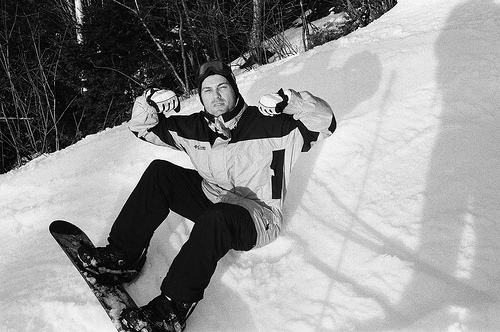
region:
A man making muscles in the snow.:
[78, 57, 337, 329]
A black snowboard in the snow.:
[48, 219, 160, 330]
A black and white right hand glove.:
[146, 84, 181, 113]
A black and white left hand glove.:
[254, 92, 289, 116]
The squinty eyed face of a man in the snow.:
[201, 74, 231, 114]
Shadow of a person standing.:
[395, 0, 498, 330]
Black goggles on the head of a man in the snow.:
[195, 62, 232, 78]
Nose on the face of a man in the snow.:
[210, 87, 221, 102]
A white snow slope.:
[3, 2, 499, 329]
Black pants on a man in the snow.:
[108, 159, 255, 304]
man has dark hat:
[185, 65, 236, 91]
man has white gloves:
[142, 80, 289, 127]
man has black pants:
[95, 173, 270, 283]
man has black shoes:
[94, 220, 158, 320]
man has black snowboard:
[29, 203, 138, 324]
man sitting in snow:
[137, 48, 307, 325]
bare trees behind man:
[0, 13, 293, 130]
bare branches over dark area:
[5, 5, 305, 166]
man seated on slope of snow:
[6, 1, 496, 326]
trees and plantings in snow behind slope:
[230, 0, 390, 70]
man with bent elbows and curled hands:
[130, 55, 336, 145]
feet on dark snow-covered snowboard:
[46, 215, 196, 330]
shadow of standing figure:
[371, 2, 491, 324]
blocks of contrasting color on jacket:
[120, 80, 335, 250]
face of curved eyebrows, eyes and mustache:
[191, 61, 237, 116]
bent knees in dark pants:
[105, 152, 261, 317]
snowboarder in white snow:
[87, 61, 337, 328]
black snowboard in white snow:
[46, 215, 155, 328]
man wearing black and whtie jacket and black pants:
[73, 56, 334, 326]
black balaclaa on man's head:
[194, 59, 241, 111]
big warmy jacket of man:
[130, 85, 340, 212]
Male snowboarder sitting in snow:
[49, 58, 337, 329]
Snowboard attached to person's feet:
[48, 218, 159, 330]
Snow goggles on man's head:
[196, 58, 231, 75]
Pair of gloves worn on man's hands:
[147, 88, 288, 118]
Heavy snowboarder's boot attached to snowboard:
[76, 240, 147, 283]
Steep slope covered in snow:
[1, 0, 498, 330]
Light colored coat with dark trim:
[128, 85, 338, 251]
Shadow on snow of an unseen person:
[349, 0, 499, 330]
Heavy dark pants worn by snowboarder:
[107, 157, 257, 304]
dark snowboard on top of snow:
[48, 219, 140, 329]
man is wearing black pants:
[74, 58, 333, 330]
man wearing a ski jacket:
[123, 90, 338, 250]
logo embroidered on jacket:
[193, 142, 206, 152]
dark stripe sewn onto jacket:
[268, 148, 287, 198]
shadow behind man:
[233, 39, 383, 226]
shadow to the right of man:
[358, 1, 498, 328]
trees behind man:
[1, 0, 403, 173]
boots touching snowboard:
[76, 240, 191, 329]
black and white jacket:
[121, 84, 338, 249]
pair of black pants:
[101, 151, 261, 303]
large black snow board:
[39, 195, 157, 330]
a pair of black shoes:
[77, 233, 172, 330]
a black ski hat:
[205, 68, 241, 98]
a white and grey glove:
[151, 87, 176, 115]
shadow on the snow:
[238, 43, 417, 208]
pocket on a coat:
[258, 155, 285, 206]